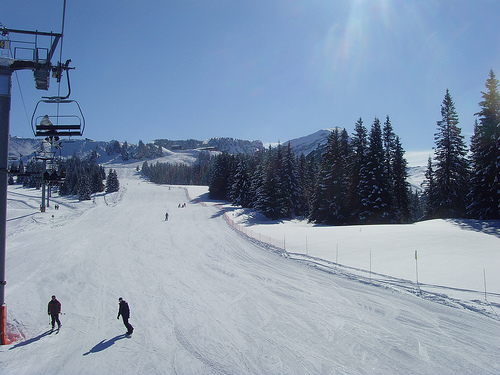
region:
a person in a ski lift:
[30, 92, 92, 151]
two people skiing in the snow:
[42, 292, 142, 337]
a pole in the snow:
[412, 249, 420, 281]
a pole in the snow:
[366, 247, 374, 279]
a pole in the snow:
[330, 243, 340, 266]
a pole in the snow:
[301, 234, 310, 258]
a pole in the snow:
[280, 232, 287, 257]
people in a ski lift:
[38, 156, 72, 190]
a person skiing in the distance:
[161, 210, 171, 223]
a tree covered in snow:
[385, 135, 413, 224]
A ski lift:
[31, 93, 88, 137]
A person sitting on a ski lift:
[35, 115, 81, 145]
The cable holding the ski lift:
[53, 12, 73, 124]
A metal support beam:
[0, 60, 14, 346]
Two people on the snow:
[44, 291, 139, 337]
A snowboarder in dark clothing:
[115, 296, 137, 332]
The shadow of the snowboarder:
[81, 330, 126, 356]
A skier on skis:
[44, 292, 69, 334]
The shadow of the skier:
[10, 328, 56, 352]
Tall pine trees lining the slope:
[156, 90, 498, 222]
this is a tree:
[414, 95, 467, 222]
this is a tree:
[374, 110, 431, 237]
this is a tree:
[346, 99, 381, 252]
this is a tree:
[296, 120, 354, 222]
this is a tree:
[252, 125, 298, 212]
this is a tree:
[239, 145, 285, 197]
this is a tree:
[145, 139, 183, 180]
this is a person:
[111, 291, 164, 358]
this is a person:
[34, 272, 93, 359]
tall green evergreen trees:
[195, 135, 480, 256]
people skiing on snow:
[47, 288, 157, 338]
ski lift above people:
[24, 55, 84, 144]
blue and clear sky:
[119, 3, 304, 67]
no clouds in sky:
[115, 15, 266, 92]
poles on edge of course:
[265, 185, 498, 292]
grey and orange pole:
[0, 78, 36, 331]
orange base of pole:
[0, 289, 32, 344]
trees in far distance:
[33, 151, 120, 210]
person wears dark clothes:
[111, 285, 157, 345]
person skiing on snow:
[81, 332, 132, 359]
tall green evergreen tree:
[423, 85, 476, 220]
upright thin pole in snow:
[409, 249, 426, 296]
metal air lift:
[28, 89, 92, 144]